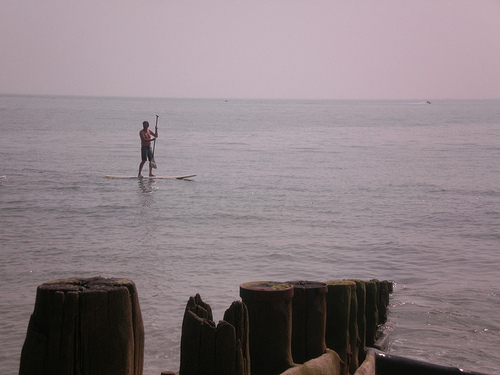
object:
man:
[138, 121, 158, 174]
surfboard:
[104, 174, 196, 179]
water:
[206, 105, 493, 256]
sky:
[0, 0, 499, 99]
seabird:
[426, 101, 431, 104]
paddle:
[150, 115, 158, 169]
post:
[179, 295, 249, 374]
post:
[239, 280, 294, 373]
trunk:
[325, 282, 350, 348]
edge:
[373, 352, 469, 374]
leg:
[139, 148, 147, 172]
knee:
[143, 160, 146, 162]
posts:
[18, 276, 144, 374]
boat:
[225, 100, 228, 103]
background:
[0, 0, 498, 171]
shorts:
[141, 146, 153, 161]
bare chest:
[145, 131, 150, 136]